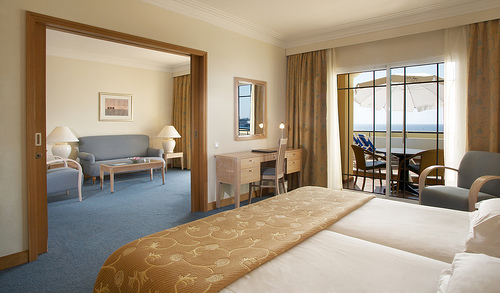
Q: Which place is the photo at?
A: It is at the hotel.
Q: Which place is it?
A: It is a hotel.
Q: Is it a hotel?
A: Yes, it is a hotel.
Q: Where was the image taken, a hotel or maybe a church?
A: It was taken at a hotel.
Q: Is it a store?
A: No, it is a hotel.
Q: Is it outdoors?
A: Yes, it is outdoors.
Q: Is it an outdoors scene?
A: Yes, it is outdoors.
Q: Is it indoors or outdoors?
A: It is outdoors.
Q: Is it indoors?
A: No, it is outdoors.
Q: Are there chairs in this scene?
A: Yes, there is a chair.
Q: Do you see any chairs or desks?
A: Yes, there is a chair.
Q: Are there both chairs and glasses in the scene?
A: No, there is a chair but no glasses.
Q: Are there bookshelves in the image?
A: No, there are no bookshelves.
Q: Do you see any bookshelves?
A: No, there are no bookshelves.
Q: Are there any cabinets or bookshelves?
A: No, there are no bookshelves or cabinets.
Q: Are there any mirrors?
A: Yes, there is a mirror.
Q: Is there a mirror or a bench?
A: Yes, there is a mirror.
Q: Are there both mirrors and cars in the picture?
A: No, there is a mirror but no cars.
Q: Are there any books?
A: No, there are no books.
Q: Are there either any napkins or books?
A: No, there are no books or napkins.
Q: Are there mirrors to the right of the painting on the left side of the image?
A: Yes, there is a mirror to the right of the painting.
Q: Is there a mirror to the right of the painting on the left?
A: Yes, there is a mirror to the right of the painting.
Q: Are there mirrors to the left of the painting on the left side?
A: No, the mirror is to the right of the painting.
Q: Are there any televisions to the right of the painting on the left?
A: No, there is a mirror to the right of the painting.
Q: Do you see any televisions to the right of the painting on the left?
A: No, there is a mirror to the right of the painting.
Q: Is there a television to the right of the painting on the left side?
A: No, there is a mirror to the right of the painting.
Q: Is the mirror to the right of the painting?
A: Yes, the mirror is to the right of the painting.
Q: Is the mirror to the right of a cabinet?
A: No, the mirror is to the right of the painting.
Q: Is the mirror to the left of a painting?
A: No, the mirror is to the right of a painting.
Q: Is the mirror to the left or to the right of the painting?
A: The mirror is to the right of the painting.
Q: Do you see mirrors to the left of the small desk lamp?
A: Yes, there is a mirror to the left of the desk lamp.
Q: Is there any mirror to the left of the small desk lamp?
A: Yes, there is a mirror to the left of the desk lamp.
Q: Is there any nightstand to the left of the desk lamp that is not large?
A: No, there is a mirror to the left of the desk lamp.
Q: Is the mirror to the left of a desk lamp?
A: Yes, the mirror is to the left of a desk lamp.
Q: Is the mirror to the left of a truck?
A: No, the mirror is to the left of a desk lamp.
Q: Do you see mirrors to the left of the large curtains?
A: Yes, there is a mirror to the left of the curtains.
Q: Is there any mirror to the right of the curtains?
A: No, the mirror is to the left of the curtains.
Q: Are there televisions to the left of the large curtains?
A: No, there is a mirror to the left of the curtains.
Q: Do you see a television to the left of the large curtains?
A: No, there is a mirror to the left of the curtains.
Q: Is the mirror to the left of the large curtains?
A: Yes, the mirror is to the left of the curtains.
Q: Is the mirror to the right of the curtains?
A: No, the mirror is to the left of the curtains.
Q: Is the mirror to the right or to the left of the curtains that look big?
A: The mirror is to the left of the curtains.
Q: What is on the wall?
A: The mirror is on the wall.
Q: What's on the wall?
A: The mirror is on the wall.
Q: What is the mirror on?
A: The mirror is on the wall.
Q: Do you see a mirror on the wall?
A: Yes, there is a mirror on the wall.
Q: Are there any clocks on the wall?
A: No, there is a mirror on the wall.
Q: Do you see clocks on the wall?
A: No, there is a mirror on the wall.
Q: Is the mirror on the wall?
A: Yes, the mirror is on the wall.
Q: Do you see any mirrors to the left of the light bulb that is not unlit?
A: Yes, there is a mirror to the left of the light bulb.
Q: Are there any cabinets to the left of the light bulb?
A: No, there is a mirror to the left of the light bulb.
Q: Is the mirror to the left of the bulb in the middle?
A: Yes, the mirror is to the left of the light bulb.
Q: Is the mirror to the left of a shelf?
A: No, the mirror is to the left of the light bulb.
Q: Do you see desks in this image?
A: Yes, there is a desk.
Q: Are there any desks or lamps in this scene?
A: Yes, there is a desk.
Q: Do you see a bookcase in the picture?
A: No, there are no bookcases.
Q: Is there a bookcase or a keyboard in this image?
A: No, there are no bookcases or keyboards.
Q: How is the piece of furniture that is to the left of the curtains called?
A: The piece of furniture is a desk.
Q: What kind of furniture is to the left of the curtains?
A: The piece of furniture is a desk.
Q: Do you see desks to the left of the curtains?
A: Yes, there is a desk to the left of the curtains.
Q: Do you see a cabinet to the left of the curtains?
A: No, there is a desk to the left of the curtains.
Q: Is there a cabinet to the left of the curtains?
A: No, there is a desk to the left of the curtains.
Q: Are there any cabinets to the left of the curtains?
A: No, there is a desk to the left of the curtains.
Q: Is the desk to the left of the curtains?
A: Yes, the desk is to the left of the curtains.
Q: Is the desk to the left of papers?
A: No, the desk is to the left of the curtains.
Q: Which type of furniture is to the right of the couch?
A: The piece of furniture is a desk.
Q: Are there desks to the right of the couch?
A: Yes, there is a desk to the right of the couch.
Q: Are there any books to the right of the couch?
A: No, there is a desk to the right of the couch.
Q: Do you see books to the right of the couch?
A: No, there is a desk to the right of the couch.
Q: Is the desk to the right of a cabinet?
A: No, the desk is to the right of the couch.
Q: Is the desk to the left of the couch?
A: No, the desk is to the right of the couch.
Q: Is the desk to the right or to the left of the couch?
A: The desk is to the right of the couch.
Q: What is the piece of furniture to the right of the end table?
A: The piece of furniture is a desk.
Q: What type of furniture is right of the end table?
A: The piece of furniture is a desk.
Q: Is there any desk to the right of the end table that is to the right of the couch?
A: Yes, there is a desk to the right of the end table.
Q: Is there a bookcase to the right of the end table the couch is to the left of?
A: No, there is a desk to the right of the end table.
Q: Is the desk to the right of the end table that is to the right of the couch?
A: Yes, the desk is to the right of the end table.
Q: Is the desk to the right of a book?
A: No, the desk is to the right of the end table.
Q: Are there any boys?
A: No, there are no boys.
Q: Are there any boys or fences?
A: No, there are no boys or fences.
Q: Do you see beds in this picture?
A: Yes, there is a bed.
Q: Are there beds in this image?
A: Yes, there is a bed.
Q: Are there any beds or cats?
A: Yes, there is a bed.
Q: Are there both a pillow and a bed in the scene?
A: Yes, there are both a bed and a pillow.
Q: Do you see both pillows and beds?
A: Yes, there are both a bed and a pillow.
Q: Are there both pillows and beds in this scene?
A: Yes, there are both a bed and a pillow.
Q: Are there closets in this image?
A: No, there are no closets.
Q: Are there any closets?
A: No, there are no closets.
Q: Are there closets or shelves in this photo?
A: No, there are no closets or shelves.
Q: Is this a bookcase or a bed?
A: This is a bed.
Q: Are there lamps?
A: Yes, there is a lamp.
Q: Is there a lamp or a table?
A: Yes, there is a lamp.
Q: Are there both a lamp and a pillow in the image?
A: Yes, there are both a lamp and a pillow.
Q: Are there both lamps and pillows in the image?
A: Yes, there are both a lamp and a pillow.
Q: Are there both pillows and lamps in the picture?
A: Yes, there are both a lamp and a pillow.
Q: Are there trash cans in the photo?
A: No, there are no trash cans.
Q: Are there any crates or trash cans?
A: No, there are no trash cans or crates.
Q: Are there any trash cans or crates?
A: No, there are no trash cans or crates.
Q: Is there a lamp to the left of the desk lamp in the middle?
A: Yes, there is a lamp to the left of the desk lamp.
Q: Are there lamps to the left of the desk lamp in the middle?
A: Yes, there is a lamp to the left of the desk lamp.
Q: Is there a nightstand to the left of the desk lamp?
A: No, there is a lamp to the left of the desk lamp.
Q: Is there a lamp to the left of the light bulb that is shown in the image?
A: Yes, there is a lamp to the left of the light bulb.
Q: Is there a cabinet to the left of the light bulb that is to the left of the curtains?
A: No, there is a lamp to the left of the light bulb.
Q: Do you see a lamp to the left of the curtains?
A: Yes, there is a lamp to the left of the curtains.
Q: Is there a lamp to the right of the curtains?
A: No, the lamp is to the left of the curtains.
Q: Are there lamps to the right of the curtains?
A: No, the lamp is to the left of the curtains.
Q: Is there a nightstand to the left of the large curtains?
A: No, there is a lamp to the left of the curtains.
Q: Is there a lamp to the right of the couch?
A: Yes, there is a lamp to the right of the couch.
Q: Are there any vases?
A: No, there are no vases.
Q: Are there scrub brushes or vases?
A: No, there are no vases or scrub brushes.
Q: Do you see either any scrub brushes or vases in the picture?
A: No, there are no vases or scrub brushes.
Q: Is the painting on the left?
A: Yes, the painting is on the left of the image.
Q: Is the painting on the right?
A: No, the painting is on the left of the image.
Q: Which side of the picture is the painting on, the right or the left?
A: The painting is on the left of the image.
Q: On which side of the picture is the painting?
A: The painting is on the left of the image.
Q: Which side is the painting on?
A: The painting is on the left of the image.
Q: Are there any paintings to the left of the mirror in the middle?
A: Yes, there is a painting to the left of the mirror.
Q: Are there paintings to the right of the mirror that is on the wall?
A: No, the painting is to the left of the mirror.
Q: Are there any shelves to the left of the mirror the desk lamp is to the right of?
A: No, there is a painting to the left of the mirror.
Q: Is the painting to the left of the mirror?
A: Yes, the painting is to the left of the mirror.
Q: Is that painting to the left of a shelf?
A: No, the painting is to the left of the mirror.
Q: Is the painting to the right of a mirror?
A: No, the painting is to the left of a mirror.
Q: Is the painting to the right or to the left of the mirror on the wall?
A: The painting is to the left of the mirror.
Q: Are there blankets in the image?
A: Yes, there is a blanket.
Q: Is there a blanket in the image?
A: Yes, there is a blanket.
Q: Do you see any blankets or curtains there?
A: Yes, there is a blanket.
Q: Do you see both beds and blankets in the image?
A: Yes, there are both a blanket and a bed.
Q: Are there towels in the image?
A: No, there are no towels.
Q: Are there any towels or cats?
A: No, there are no towels or cats.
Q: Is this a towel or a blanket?
A: This is a blanket.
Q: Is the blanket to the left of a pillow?
A: Yes, the blanket is to the left of a pillow.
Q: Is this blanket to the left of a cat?
A: No, the blanket is to the left of a pillow.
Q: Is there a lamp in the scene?
A: Yes, there is a lamp.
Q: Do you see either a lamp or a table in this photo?
A: Yes, there is a lamp.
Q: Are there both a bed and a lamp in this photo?
A: Yes, there are both a lamp and a bed.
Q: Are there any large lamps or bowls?
A: Yes, there is a large lamp.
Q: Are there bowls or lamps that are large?
A: Yes, the lamp is large.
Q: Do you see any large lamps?
A: Yes, there is a large lamp.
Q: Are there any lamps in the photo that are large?
A: Yes, there is a lamp that is large.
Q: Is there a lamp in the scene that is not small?
A: Yes, there is a large lamp.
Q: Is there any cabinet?
A: No, there are no cabinets.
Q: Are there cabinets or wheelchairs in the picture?
A: No, there are no cabinets or wheelchairs.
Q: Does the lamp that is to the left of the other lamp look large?
A: Yes, the lamp is large.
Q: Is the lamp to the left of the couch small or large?
A: The lamp is large.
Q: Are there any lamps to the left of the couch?
A: Yes, there is a lamp to the left of the couch.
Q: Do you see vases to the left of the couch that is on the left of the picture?
A: No, there is a lamp to the left of the couch.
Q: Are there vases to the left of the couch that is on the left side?
A: No, there is a lamp to the left of the couch.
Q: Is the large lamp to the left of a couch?
A: Yes, the lamp is to the left of a couch.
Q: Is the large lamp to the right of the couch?
A: No, the lamp is to the left of the couch.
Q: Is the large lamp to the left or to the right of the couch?
A: The lamp is to the left of the couch.